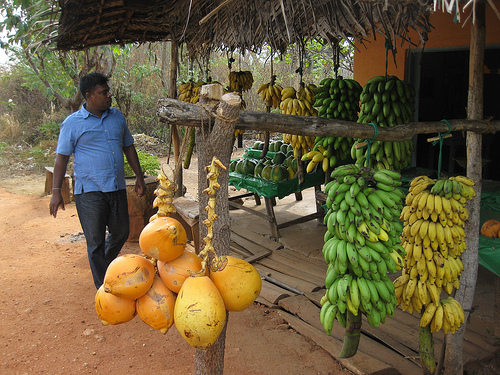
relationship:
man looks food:
[44, 69, 147, 292] [301, 65, 413, 174]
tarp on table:
[224, 171, 325, 198] [235, 169, 327, 238]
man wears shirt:
[44, 69, 147, 292] [54, 101, 132, 192]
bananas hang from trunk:
[405, 175, 479, 337] [161, 90, 497, 144]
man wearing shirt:
[48, 72, 148, 293] [60, 102, 127, 191]